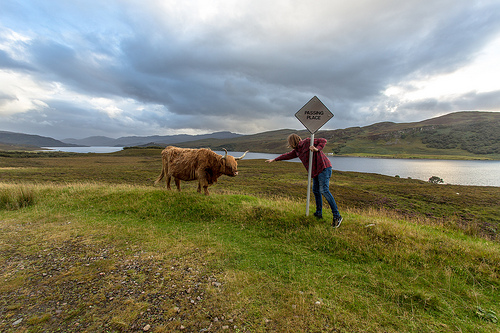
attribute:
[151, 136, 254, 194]
bull — brown, furry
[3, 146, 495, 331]
grass — green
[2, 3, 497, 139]
sky — cloudy, overcast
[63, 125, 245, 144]
hill — in background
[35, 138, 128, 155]
water — blue, cool, running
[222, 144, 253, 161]
horns — long, white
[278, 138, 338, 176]
sweater — red, plaid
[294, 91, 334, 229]
sign — diamond, black, white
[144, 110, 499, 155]
mountains — in background, rolling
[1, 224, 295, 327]
pebbles — scattered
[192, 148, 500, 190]
lake — in background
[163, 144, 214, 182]
fur — shaggy, brown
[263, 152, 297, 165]
arm — reaching out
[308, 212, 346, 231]
shoes — colored